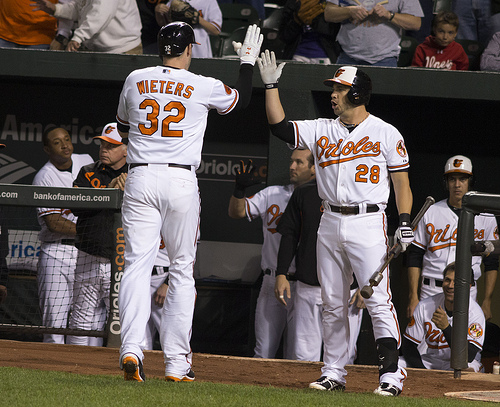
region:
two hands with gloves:
[230, 18, 290, 83]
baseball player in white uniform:
[108, 15, 214, 382]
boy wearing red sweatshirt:
[410, 13, 470, 75]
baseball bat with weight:
[358, 191, 440, 301]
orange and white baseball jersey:
[292, 111, 404, 216]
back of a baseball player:
[120, 18, 215, 390]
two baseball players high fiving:
[104, 14, 408, 215]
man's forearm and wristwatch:
[373, 0, 424, 32]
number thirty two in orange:
[135, 97, 187, 140]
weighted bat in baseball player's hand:
[299, 61, 437, 397]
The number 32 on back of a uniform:
[135, 96, 189, 143]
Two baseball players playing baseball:
[113, 16, 437, 399]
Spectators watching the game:
[2, 0, 499, 74]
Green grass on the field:
[1, 361, 497, 403]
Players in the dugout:
[26, 120, 497, 372]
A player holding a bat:
[253, 45, 439, 398]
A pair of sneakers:
[115, 349, 199, 389]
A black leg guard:
[369, 332, 413, 378]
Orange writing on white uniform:
[314, 127, 389, 189]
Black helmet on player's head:
[153, 17, 204, 75]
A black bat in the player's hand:
[353, 197, 437, 302]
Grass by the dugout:
[5, 362, 472, 405]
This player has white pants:
[120, 168, 198, 364]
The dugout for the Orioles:
[5, 53, 499, 370]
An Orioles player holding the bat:
[258, 50, 430, 403]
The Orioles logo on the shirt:
[312, 135, 384, 161]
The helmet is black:
[158, 23, 198, 46]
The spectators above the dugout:
[1, 0, 493, 57]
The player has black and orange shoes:
[116, 353, 197, 380]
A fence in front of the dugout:
[1, 189, 118, 341]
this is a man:
[119, 33, 221, 360]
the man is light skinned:
[254, 92, 287, 119]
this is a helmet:
[159, 25, 196, 43]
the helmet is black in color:
[163, 25, 185, 40]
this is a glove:
[261, 53, 287, 86]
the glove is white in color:
[261, 63, 288, 75]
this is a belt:
[328, 205, 354, 214]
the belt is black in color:
[335, 205, 359, 215]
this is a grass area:
[21, 371, 85, 404]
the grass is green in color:
[231, 380, 261, 403]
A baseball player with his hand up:
[112, 20, 264, 383]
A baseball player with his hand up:
[256, 48, 437, 396]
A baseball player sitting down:
[397, 260, 487, 367]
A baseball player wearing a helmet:
[405, 154, 498, 322]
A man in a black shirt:
[275, 178, 367, 365]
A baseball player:
[226, 144, 318, 356]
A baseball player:
[31, 126, 94, 346]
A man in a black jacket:
[65, 118, 132, 342]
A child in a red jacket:
[415, 12, 471, 72]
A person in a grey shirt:
[325, 0, 425, 67]